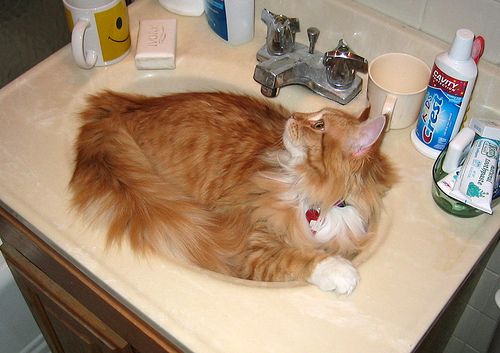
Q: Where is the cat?
A: In the sink.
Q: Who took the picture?
A: The photographer.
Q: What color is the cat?
A: Orange.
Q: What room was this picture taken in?
A: The bathroom.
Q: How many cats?
A: One.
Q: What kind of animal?
A: Cat.